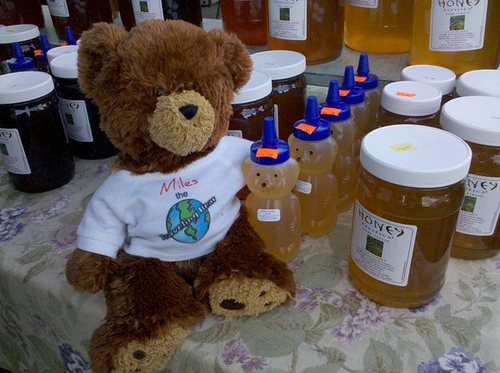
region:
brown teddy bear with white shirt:
[67, 28, 297, 371]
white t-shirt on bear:
[77, 135, 252, 257]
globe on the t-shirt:
[169, 202, 211, 244]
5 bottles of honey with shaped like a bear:
[241, 53, 377, 265]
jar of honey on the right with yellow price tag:
[349, 127, 469, 309]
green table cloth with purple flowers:
[1, 155, 491, 371]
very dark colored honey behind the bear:
[2, 29, 116, 190]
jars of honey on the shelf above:
[49, 3, 499, 73]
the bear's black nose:
[178, 104, 197, 119]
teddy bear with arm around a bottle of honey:
[64, 23, 297, 371]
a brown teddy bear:
[65, 25, 291, 346]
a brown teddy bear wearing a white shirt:
[73, 56, 291, 335]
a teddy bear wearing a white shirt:
[86, 60, 296, 352]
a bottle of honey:
[331, 112, 462, 354]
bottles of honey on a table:
[378, 52, 498, 271]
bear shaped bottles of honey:
[235, 62, 396, 286]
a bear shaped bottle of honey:
[240, 71, 297, 306]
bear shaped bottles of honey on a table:
[216, 60, 399, 225]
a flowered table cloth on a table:
[35, 228, 410, 370]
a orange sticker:
[241, 143, 298, 170]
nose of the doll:
[146, 86, 234, 172]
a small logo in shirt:
[160, 189, 245, 264]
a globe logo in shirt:
[122, 175, 251, 242]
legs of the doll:
[196, 265, 308, 337]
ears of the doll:
[59, 15, 156, 89]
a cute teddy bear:
[71, 8, 267, 360]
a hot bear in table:
[59, 10, 385, 363]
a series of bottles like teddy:
[242, 55, 375, 249]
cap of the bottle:
[242, 85, 297, 173]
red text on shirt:
[138, 172, 209, 204]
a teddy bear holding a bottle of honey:
[66, 15, 296, 366]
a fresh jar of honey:
[345, 120, 475, 310]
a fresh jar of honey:
[0, 70, 70, 190]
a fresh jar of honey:
[440, 91, 495, 258]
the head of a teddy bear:
[72, 22, 253, 171]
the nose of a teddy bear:
[174, 96, 207, 124]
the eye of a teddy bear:
[151, 81, 167, 103]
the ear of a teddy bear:
[60, 25, 127, 97]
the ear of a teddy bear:
[212, 25, 254, 94]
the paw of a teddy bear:
[59, 246, 111, 296]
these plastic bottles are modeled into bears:
[247, 48, 401, 280]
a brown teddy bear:
[49, 21, 331, 370]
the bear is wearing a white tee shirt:
[36, 12, 291, 370]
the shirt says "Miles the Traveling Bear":
[81, 154, 294, 299]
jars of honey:
[359, 47, 494, 320]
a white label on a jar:
[336, 195, 438, 316]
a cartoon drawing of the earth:
[159, 192, 224, 249]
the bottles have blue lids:
[238, 108, 315, 279]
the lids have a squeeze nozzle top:
[236, 106, 319, 263]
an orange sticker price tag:
[239, 137, 294, 175]